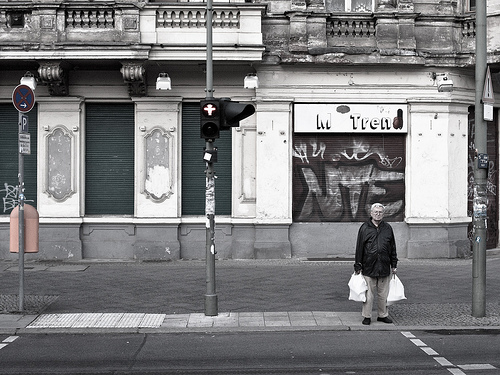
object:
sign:
[293, 104, 409, 134]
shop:
[1, 100, 476, 258]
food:
[387, 275, 405, 304]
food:
[345, 272, 365, 304]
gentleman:
[354, 203, 398, 325]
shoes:
[363, 318, 372, 325]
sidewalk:
[11, 248, 498, 322]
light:
[198, 98, 220, 140]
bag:
[386, 273, 406, 306]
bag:
[347, 271, 368, 302]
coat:
[354, 217, 399, 278]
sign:
[18, 132, 31, 155]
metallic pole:
[17, 81, 25, 311]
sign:
[20, 115, 29, 131]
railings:
[0, 4, 479, 59]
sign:
[12, 85, 35, 113]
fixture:
[199, 96, 256, 141]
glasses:
[370, 211, 384, 214]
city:
[4, 4, 497, 260]